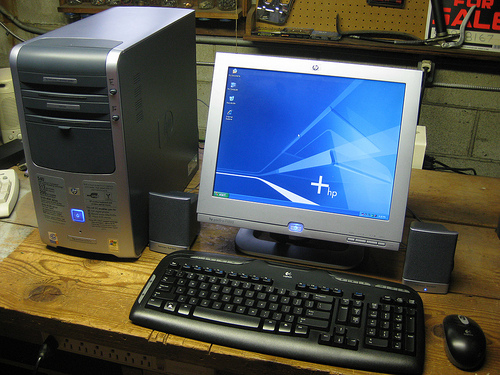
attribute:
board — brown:
[262, 0, 429, 33]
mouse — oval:
[434, 304, 498, 364]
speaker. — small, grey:
[390, 192, 463, 287]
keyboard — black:
[103, 242, 446, 364]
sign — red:
[426, 1, 498, 52]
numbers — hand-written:
[426, 25, 498, 46]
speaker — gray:
[393, 220, 470, 305]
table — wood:
[6, 217, 130, 353]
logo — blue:
[67, 207, 87, 226]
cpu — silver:
[9, 13, 189, 255]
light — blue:
[71, 209, 83, 224]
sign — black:
[423, 2, 498, 62]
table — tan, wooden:
[23, 259, 111, 316]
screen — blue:
[274, 102, 364, 176]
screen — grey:
[194, 45, 428, 271]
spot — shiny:
[449, 336, 468, 350]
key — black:
[186, 287, 196, 297]